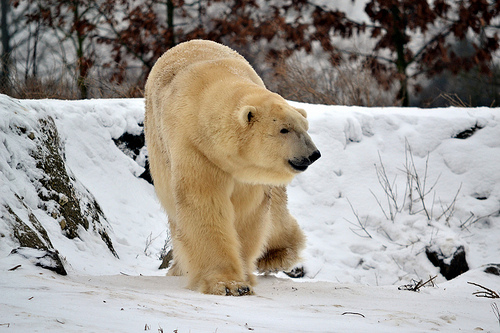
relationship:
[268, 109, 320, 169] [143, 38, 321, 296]
face of bear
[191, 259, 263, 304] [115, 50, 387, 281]
foot of bear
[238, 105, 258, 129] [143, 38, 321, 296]
ear of bear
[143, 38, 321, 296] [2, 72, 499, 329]
bear walking in snow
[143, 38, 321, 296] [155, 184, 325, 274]
bear walking all fours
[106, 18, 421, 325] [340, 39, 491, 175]
bear found in colder regions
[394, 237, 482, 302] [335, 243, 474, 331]
rock laying ground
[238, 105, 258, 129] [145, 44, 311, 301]
ear of bear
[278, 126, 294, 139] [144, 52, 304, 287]
eye of bear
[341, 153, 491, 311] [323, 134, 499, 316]
stick plant covered snow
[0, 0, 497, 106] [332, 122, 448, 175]
trees covered snow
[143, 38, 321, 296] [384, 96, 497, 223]
bear on snow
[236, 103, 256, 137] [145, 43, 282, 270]
ear on polar bear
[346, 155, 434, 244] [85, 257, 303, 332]
snow on ground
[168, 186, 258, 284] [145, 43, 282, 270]
legs on polar bear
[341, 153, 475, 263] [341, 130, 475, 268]
branches sticking out of snow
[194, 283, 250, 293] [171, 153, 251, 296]
edge of leg